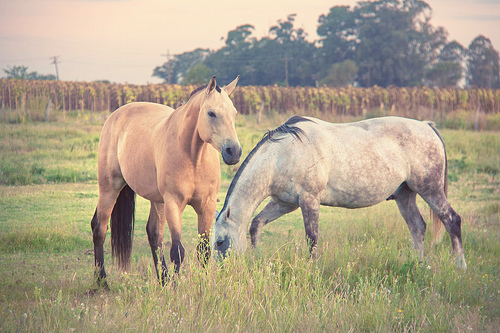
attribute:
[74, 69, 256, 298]
horse — grazing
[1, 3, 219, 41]
sky — pink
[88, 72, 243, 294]
horse — light, brown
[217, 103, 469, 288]
horse — gray, black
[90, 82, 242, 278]
horse — brown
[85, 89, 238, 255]
horse — staring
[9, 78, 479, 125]
corn — growing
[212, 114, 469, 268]
horse — black, tan, grey, eating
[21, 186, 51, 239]
grass — green, brown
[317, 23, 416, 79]
trees — tall, green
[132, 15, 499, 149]
trees — green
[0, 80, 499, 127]
foliage — green, brown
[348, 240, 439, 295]
grass — long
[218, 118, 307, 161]
mane — black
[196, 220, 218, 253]
flowers — tiny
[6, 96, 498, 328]
grass — green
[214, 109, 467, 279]
greyhorse — gray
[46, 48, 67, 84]
pole — sideways